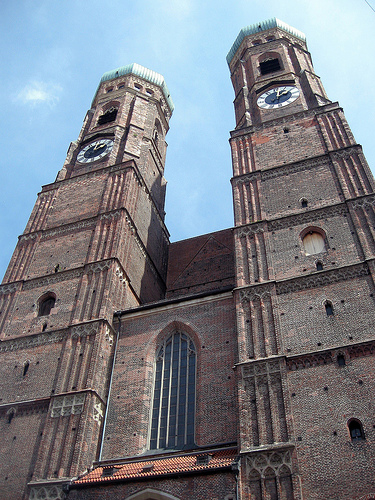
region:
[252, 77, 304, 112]
white and black clock on a building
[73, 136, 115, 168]
white and black clock on a building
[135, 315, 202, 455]
large ornate window on a building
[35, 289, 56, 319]
small ornate window on a building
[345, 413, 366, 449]
small ornate window on a building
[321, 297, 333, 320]
small ornate window on a building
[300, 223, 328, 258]
small ornate window on a building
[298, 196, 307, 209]
small ornate window on a building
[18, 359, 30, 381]
small ornate window on a building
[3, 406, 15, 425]
small ornate window on a building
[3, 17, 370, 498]
bilateral clock towers are on the building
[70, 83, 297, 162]
the clock faces are black and white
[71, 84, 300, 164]
the clocks' hands are gold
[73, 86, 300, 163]
the roman numerals of the clocks are black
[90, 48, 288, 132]
arched windows are on the towers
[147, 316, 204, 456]
a tall arched window is in the center of the building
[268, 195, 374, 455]
holes are left on the building from marble removal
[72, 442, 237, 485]
red clay tile is on the roof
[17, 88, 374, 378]
decorative parapets are on the structure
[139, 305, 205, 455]
mullions are in the arched window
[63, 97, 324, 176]
two clocks on towers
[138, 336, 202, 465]
large and arched window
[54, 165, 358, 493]
wall is brown brick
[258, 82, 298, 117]
black and white clock face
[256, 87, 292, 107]
gold roman numerals on clock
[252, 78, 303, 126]
gold hands on clock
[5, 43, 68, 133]
blue and white sky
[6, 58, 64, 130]
tiny thin clouds in sky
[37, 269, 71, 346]
small windows in tower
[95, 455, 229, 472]
red roof on tower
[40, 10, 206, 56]
clear blue sky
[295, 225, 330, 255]
arch made on building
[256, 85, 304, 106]
clock on building wall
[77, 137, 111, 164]
clock with round dial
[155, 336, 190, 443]
Glass window of building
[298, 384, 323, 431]
building wall made with bricks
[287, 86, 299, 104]
Roman number mentioned on clock dail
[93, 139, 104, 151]
Hands of the clock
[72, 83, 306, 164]
Building with two clock on its wall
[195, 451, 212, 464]
chimney made on roof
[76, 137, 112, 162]
a clock is on the tower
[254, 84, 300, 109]
a clock is on the tower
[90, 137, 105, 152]
the dials are gold in tone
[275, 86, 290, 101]
the dials are gold in tone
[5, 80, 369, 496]
the tower is made of brick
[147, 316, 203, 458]
a large arched window in in front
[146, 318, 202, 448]
the window is of stained glass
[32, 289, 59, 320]
a window is high above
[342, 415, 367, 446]
a small window is on the wall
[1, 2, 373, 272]
the sky is blue in color